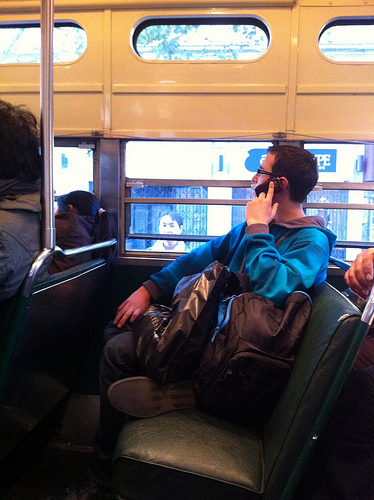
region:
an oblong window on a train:
[128, 13, 271, 62]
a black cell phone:
[253, 178, 283, 200]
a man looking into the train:
[146, 210, 188, 250]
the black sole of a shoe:
[107, 376, 217, 420]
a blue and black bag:
[190, 287, 310, 430]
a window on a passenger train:
[118, 140, 274, 262]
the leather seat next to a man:
[119, 400, 263, 491]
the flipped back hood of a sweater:
[280, 212, 337, 251]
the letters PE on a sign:
[315, 153, 331, 167]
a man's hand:
[340, 247, 372, 295]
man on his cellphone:
[87, 130, 343, 498]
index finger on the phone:
[265, 180, 275, 197]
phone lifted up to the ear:
[249, 172, 288, 199]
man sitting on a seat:
[86, 125, 341, 468]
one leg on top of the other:
[71, 297, 219, 497]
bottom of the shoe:
[104, 372, 199, 420]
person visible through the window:
[143, 208, 185, 249]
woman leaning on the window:
[43, 174, 131, 274]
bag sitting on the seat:
[186, 288, 313, 434]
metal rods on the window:
[118, 172, 259, 245]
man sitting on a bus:
[92, 123, 337, 454]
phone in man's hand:
[253, 175, 290, 203]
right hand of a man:
[114, 283, 159, 339]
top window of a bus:
[118, 14, 273, 65]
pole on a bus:
[30, 1, 80, 272]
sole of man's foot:
[100, 361, 206, 421]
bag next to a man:
[198, 279, 300, 467]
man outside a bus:
[142, 204, 190, 251]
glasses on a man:
[248, 160, 281, 189]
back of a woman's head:
[58, 182, 123, 257]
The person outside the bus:
[147, 206, 191, 254]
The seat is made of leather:
[122, 408, 315, 494]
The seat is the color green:
[126, 431, 310, 497]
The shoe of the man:
[103, 376, 205, 416]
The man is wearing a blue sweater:
[142, 212, 337, 346]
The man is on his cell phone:
[243, 163, 298, 237]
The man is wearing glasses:
[248, 157, 287, 184]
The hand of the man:
[114, 290, 144, 330]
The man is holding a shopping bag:
[127, 259, 236, 387]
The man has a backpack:
[193, 274, 315, 431]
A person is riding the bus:
[140, 140, 367, 491]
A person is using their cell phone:
[139, 135, 342, 497]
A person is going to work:
[153, 138, 343, 496]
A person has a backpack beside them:
[166, 140, 360, 486]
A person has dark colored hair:
[163, 136, 346, 490]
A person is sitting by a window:
[144, 135, 357, 491]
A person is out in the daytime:
[142, 135, 369, 426]